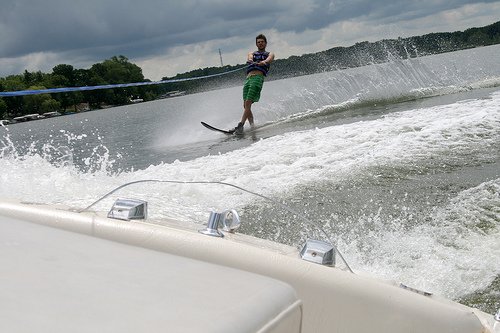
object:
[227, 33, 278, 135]
man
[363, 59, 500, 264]
water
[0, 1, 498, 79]
sky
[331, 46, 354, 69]
trees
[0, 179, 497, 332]
boat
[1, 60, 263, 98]
rope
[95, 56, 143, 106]
trees